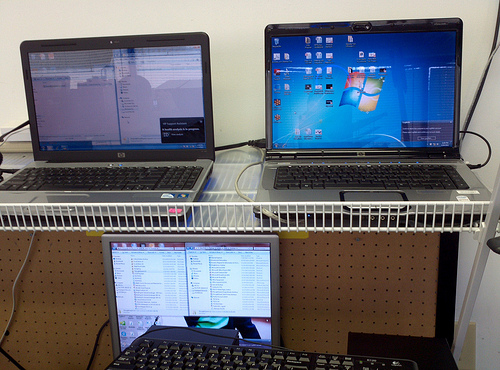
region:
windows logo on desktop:
[332, 71, 406, 116]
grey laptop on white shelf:
[250, 19, 495, 222]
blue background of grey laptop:
[264, 26, 454, 148]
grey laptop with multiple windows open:
[12, 48, 208, 224]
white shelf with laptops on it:
[132, 179, 496, 262]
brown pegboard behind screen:
[290, 241, 440, 310]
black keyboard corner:
[97, 328, 422, 363]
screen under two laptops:
[91, 231, 355, 344]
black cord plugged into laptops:
[451, 132, 487, 192]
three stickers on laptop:
[123, 179, 193, 230]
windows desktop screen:
[269, 34, 453, 146]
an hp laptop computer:
[4, 26, 214, 231]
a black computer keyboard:
[94, 325, 416, 368]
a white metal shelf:
[0, 146, 480, 245]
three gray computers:
[4, 5, 490, 363]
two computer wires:
[210, 129, 268, 211]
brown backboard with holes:
[6, 212, 441, 360]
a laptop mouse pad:
[334, 186, 413, 216]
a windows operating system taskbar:
[40, 136, 210, 149]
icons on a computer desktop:
[277, 35, 396, 135]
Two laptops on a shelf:
[13, 19, 477, 216]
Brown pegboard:
[310, 241, 423, 322]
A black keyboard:
[107, 320, 281, 365]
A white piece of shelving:
[4, 144, 483, 235]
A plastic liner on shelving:
[200, 151, 266, 226]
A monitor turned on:
[94, 223, 298, 363]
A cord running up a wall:
[2, 226, 47, 335]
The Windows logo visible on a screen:
[330, 60, 400, 118]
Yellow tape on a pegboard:
[80, 226, 314, 242]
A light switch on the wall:
[450, 310, 490, 360]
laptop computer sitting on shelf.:
[0, 24, 227, 241]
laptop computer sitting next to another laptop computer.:
[254, 8, 494, 228]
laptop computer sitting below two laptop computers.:
[92, 224, 294, 366]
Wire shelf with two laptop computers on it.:
[0, 139, 497, 266]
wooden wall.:
[306, 271, 411, 319]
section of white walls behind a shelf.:
[221, 59, 246, 98]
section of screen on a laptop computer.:
[330, 79, 395, 130]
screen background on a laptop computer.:
[71, 73, 143, 130]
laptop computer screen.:
[147, 283, 242, 310]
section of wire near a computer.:
[461, 59, 481, 111]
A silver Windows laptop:
[253, 17, 495, 220]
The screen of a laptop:
[266, 28, 453, 148]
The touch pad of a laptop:
[336, 187, 410, 213]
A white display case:
[1, 196, 483, 235]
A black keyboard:
[105, 332, 424, 368]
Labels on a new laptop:
[155, 186, 190, 216]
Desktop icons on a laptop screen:
[292, 32, 339, 109]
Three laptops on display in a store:
[8, 13, 485, 366]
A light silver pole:
[448, 218, 497, 358]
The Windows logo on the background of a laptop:
[337, 70, 386, 116]